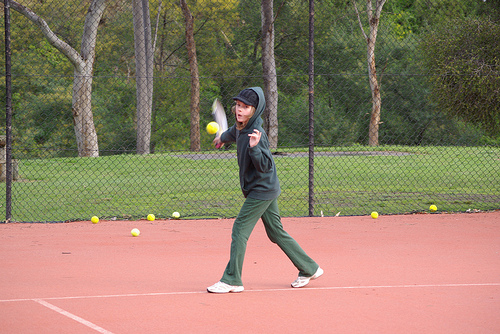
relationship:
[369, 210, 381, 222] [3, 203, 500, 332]
ball on ground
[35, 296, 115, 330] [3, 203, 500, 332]
line on ground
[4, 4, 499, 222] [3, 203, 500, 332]
fence on ground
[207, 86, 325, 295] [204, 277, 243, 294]
girl has shoe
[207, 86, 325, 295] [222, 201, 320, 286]
girl has trouser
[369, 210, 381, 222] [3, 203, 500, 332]
ball lying on ground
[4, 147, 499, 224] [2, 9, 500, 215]
field in background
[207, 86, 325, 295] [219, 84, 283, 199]
girl wearing hoodie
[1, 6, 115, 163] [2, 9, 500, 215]
tree in background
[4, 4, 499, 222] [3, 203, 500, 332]
fence enclosing ground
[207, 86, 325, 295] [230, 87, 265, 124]
girl has head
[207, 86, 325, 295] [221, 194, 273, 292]
girl has leg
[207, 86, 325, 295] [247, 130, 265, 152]
girl has hand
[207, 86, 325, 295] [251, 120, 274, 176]
girl has arm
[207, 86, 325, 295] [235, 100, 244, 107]
girl has eye